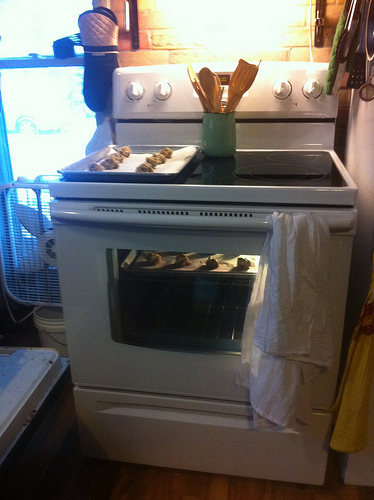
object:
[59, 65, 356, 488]
stove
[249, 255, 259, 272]
light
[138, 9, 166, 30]
bricks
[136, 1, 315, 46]
wall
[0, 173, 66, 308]
box fan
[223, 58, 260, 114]
utensils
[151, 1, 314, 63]
glow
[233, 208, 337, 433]
towel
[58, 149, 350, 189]
surface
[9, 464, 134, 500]
floor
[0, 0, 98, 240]
window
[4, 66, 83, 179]
light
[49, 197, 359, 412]
oven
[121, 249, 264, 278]
tray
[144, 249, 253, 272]
dough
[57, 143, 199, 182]
top tray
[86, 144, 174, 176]
top dough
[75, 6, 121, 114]
mitt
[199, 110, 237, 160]
holder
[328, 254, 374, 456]
handtowel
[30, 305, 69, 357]
pail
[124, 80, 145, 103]
knobs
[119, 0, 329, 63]
brick wall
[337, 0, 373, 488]
cabinet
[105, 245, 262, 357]
glass window